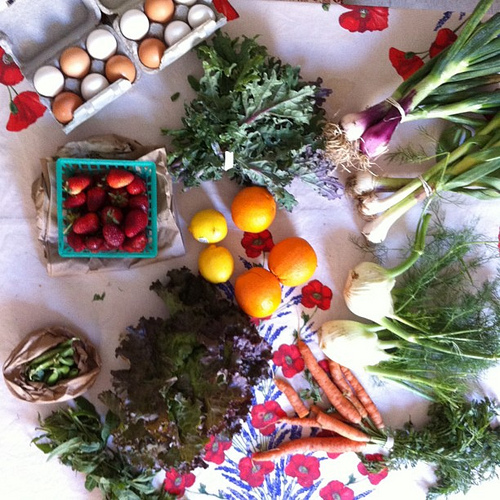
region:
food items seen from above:
[22, 28, 478, 438]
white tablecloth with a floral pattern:
[305, 1, 442, 71]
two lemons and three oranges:
[187, 180, 314, 315]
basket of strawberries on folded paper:
[35, 137, 180, 268]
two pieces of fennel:
[335, 230, 490, 375]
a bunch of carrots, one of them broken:
[256, 360, 416, 465]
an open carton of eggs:
[30, 2, 225, 112]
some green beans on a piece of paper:
[10, 320, 91, 402]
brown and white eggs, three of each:
[30, 30, 131, 120]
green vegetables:
[195, 71, 490, 172]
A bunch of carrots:
[254, 334, 499, 471]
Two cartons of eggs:
[3, 1, 235, 133]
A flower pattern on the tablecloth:
[157, 224, 396, 499]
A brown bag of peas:
[0, 323, 102, 403]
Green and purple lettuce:
[95, 264, 281, 466]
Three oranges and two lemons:
[182, 185, 320, 320]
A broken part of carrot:
[269, 368, 314, 420]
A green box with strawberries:
[53, 155, 159, 260]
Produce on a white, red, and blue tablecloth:
[2, 0, 498, 499]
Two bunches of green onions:
[322, 3, 498, 244]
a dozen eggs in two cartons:
[25, 0, 225, 134]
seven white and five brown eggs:
[25, 0, 227, 146]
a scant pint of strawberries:
[50, 155, 157, 264]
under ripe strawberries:
[55, 168, 140, 198]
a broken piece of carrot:
[271, 367, 329, 432]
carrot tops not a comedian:
[390, 395, 499, 499]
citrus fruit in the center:
[187, 184, 317, 329]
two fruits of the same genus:
[187, 181, 320, 321]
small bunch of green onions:
[345, 165, 435, 245]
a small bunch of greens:
[166, 38, 334, 187]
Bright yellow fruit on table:
[180, 204, 232, 243]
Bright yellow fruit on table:
[184, 248, 236, 284]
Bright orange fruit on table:
[220, 178, 280, 235]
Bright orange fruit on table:
[267, 235, 324, 292]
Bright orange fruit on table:
[234, 260, 277, 319]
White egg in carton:
[27, 64, 63, 96]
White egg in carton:
[79, 23, 113, 54]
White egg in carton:
[114, 9, 144, 37]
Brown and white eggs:
[18, 23, 138, 127]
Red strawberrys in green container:
[38, 154, 163, 269]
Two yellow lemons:
[188, 207, 233, 284]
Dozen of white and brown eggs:
[34, 0, 211, 122]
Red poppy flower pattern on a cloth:
[131, 224, 396, 498]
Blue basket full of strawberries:
[50, 153, 162, 258]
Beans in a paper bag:
[1, 324, 98, 403]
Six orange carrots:
[253, 338, 493, 498]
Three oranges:
[229, 181, 319, 318]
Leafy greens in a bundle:
[171, 39, 341, 211]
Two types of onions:
[311, 10, 497, 252]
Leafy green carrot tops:
[389, 401, 497, 497]